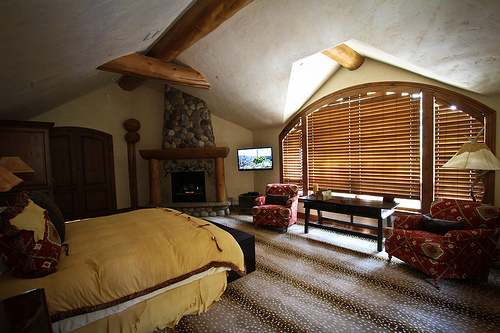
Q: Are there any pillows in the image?
A: Yes, there is a pillow.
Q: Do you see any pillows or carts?
A: Yes, there is a pillow.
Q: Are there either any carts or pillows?
A: Yes, there is a pillow.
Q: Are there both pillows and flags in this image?
A: No, there is a pillow but no flags.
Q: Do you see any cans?
A: No, there are no cans.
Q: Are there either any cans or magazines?
A: No, there are no cans or magazines.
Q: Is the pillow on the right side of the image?
A: Yes, the pillow is on the right of the image.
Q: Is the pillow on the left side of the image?
A: No, the pillow is on the right of the image.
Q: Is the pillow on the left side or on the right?
A: The pillow is on the right of the image.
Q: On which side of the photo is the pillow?
A: The pillow is on the right of the image.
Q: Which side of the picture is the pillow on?
A: The pillow is on the right of the image.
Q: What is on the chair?
A: The pillow is on the chair.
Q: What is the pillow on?
A: The pillow is on the chair.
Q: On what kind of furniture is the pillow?
A: The pillow is on the chair.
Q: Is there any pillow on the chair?
A: Yes, there is a pillow on the chair.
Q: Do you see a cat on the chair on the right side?
A: No, there is a pillow on the chair.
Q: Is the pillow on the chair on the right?
A: Yes, the pillow is on the chair.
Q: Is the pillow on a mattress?
A: No, the pillow is on the chair.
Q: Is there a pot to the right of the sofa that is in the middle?
A: No, there is a pillow to the right of the sofa.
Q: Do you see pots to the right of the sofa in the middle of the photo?
A: No, there is a pillow to the right of the sofa.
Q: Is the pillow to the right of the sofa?
A: Yes, the pillow is to the right of the sofa.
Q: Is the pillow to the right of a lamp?
A: No, the pillow is to the right of the sofa.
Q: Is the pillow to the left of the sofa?
A: No, the pillow is to the right of the sofa.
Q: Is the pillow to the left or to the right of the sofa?
A: The pillow is to the right of the sofa.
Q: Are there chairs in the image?
A: Yes, there is a chair.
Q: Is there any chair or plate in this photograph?
A: Yes, there is a chair.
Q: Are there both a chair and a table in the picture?
A: Yes, there are both a chair and a table.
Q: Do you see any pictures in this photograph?
A: No, there are no pictures.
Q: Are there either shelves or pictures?
A: No, there are no pictures or shelves.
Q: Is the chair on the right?
A: Yes, the chair is on the right of the image.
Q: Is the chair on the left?
A: No, the chair is on the right of the image.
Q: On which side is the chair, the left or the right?
A: The chair is on the right of the image.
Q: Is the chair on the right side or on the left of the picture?
A: The chair is on the right of the image.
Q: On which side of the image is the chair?
A: The chair is on the right of the image.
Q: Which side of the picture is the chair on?
A: The chair is on the right of the image.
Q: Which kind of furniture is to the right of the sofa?
A: The piece of furniture is a chair.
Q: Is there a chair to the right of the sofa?
A: Yes, there is a chair to the right of the sofa.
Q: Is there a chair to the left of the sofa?
A: No, the chair is to the right of the sofa.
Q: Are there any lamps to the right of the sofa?
A: No, there is a chair to the right of the sofa.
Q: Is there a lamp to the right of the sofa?
A: No, there is a chair to the right of the sofa.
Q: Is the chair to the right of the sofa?
A: Yes, the chair is to the right of the sofa.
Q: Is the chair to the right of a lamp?
A: No, the chair is to the right of the sofa.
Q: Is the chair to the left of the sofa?
A: No, the chair is to the right of the sofa.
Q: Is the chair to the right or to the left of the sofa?
A: The chair is to the right of the sofa.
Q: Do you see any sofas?
A: Yes, there is a sofa.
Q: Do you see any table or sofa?
A: Yes, there is a sofa.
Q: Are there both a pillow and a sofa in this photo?
A: Yes, there are both a sofa and a pillow.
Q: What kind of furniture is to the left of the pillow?
A: The piece of furniture is a sofa.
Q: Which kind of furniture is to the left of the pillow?
A: The piece of furniture is a sofa.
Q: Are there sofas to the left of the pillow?
A: Yes, there is a sofa to the left of the pillow.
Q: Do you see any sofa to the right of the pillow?
A: No, the sofa is to the left of the pillow.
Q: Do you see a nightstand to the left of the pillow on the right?
A: No, there is a sofa to the left of the pillow.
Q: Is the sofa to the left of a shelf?
A: No, the sofa is to the left of the pillow.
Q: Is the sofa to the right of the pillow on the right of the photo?
A: No, the sofa is to the left of the pillow.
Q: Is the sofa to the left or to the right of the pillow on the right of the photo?
A: The sofa is to the left of the pillow.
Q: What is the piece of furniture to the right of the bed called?
A: The piece of furniture is a sofa.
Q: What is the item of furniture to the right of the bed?
A: The piece of furniture is a sofa.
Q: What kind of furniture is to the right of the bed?
A: The piece of furniture is a sofa.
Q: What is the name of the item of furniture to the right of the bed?
A: The piece of furniture is a sofa.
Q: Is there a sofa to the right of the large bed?
A: Yes, there is a sofa to the right of the bed.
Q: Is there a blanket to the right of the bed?
A: No, there is a sofa to the right of the bed.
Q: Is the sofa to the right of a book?
A: No, the sofa is to the right of a bed.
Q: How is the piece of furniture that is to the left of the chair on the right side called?
A: The piece of furniture is a sofa.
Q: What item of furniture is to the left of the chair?
A: The piece of furniture is a sofa.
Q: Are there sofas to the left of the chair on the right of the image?
A: Yes, there is a sofa to the left of the chair.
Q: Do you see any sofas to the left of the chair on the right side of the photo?
A: Yes, there is a sofa to the left of the chair.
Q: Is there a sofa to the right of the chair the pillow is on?
A: No, the sofa is to the left of the chair.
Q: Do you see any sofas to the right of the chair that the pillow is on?
A: No, the sofa is to the left of the chair.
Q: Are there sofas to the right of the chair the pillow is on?
A: No, the sofa is to the left of the chair.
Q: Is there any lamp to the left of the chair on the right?
A: No, there is a sofa to the left of the chair.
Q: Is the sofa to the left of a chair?
A: Yes, the sofa is to the left of a chair.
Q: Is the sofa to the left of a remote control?
A: No, the sofa is to the left of a chair.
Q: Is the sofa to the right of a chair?
A: No, the sofa is to the left of a chair.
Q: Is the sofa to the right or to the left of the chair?
A: The sofa is to the left of the chair.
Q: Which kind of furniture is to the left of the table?
A: The piece of furniture is a sofa.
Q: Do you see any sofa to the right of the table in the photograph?
A: No, the sofa is to the left of the table.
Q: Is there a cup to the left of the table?
A: No, there is a sofa to the left of the table.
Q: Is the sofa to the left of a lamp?
A: No, the sofa is to the left of a table.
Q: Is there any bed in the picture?
A: Yes, there is a bed.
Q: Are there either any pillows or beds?
A: Yes, there is a bed.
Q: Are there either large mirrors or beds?
A: Yes, there is a large bed.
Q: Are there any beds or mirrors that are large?
A: Yes, the bed is large.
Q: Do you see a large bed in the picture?
A: Yes, there is a large bed.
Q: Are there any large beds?
A: Yes, there is a large bed.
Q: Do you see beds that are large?
A: Yes, there is a bed that is large.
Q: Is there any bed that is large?
A: Yes, there is a bed that is large.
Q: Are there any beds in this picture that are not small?
A: Yes, there is a large bed.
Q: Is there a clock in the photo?
A: No, there are no clocks.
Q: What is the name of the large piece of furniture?
A: The piece of furniture is a bed.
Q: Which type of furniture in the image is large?
A: The furniture is a bed.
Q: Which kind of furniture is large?
A: The furniture is a bed.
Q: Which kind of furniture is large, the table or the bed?
A: The bed is large.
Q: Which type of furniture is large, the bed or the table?
A: The bed is large.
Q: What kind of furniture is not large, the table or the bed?
A: The table is not large.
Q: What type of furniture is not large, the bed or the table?
A: The table is not large.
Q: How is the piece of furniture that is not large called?
A: The piece of furniture is a table.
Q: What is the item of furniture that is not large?
A: The piece of furniture is a table.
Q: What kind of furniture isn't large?
A: The furniture is a table.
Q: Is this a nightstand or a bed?
A: This is a bed.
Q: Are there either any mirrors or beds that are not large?
A: No, there is a bed but it is large.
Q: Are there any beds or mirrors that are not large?
A: No, there is a bed but it is large.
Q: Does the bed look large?
A: Yes, the bed is large.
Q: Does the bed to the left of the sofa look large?
A: Yes, the bed is large.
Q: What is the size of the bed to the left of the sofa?
A: The bed is large.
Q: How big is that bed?
A: The bed is large.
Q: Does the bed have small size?
A: No, the bed is large.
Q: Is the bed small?
A: No, the bed is large.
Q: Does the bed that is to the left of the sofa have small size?
A: No, the bed is large.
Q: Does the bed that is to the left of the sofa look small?
A: No, the bed is large.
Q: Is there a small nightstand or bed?
A: No, there is a bed but it is large.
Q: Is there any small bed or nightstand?
A: No, there is a bed but it is large.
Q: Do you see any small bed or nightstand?
A: No, there is a bed but it is large.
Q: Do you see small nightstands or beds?
A: No, there is a bed but it is large.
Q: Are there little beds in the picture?
A: No, there is a bed but it is large.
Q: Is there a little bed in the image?
A: No, there is a bed but it is large.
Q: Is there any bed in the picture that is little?
A: No, there is a bed but it is large.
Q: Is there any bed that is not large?
A: No, there is a bed but it is large.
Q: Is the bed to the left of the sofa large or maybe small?
A: The bed is large.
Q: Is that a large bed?
A: Yes, that is a large bed.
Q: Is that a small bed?
A: No, that is a large bed.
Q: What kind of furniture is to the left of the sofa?
A: The piece of furniture is a bed.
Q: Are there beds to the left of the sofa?
A: Yes, there is a bed to the left of the sofa.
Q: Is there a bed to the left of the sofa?
A: Yes, there is a bed to the left of the sofa.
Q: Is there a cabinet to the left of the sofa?
A: No, there is a bed to the left of the sofa.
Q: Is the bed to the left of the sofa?
A: Yes, the bed is to the left of the sofa.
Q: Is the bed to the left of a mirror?
A: No, the bed is to the left of the sofa.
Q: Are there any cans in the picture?
A: No, there are no cans.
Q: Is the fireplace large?
A: Yes, the fireplace is large.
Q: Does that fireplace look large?
A: Yes, the fireplace is large.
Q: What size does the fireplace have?
A: The fireplace has large size.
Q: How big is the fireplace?
A: The fireplace is large.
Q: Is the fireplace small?
A: No, the fireplace is large.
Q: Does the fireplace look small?
A: No, the fireplace is large.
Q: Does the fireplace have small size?
A: No, the fireplace is large.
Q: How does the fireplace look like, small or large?
A: The fireplace is large.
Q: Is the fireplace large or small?
A: The fireplace is large.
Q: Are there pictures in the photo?
A: No, there are no pictures.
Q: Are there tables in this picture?
A: Yes, there is a table.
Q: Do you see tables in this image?
A: Yes, there is a table.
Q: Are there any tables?
A: Yes, there is a table.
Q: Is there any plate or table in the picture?
A: Yes, there is a table.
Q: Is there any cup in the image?
A: No, there are no cups.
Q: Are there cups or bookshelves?
A: No, there are no cups or bookshelves.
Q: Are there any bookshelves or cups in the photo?
A: No, there are no cups or bookshelves.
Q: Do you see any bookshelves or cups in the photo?
A: No, there are no cups or bookshelves.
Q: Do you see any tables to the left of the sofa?
A: No, the table is to the right of the sofa.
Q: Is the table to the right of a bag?
A: No, the table is to the right of a sofa.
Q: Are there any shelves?
A: No, there are no shelves.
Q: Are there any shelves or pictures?
A: No, there are no shelves or pictures.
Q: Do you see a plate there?
A: No, there are no plates.